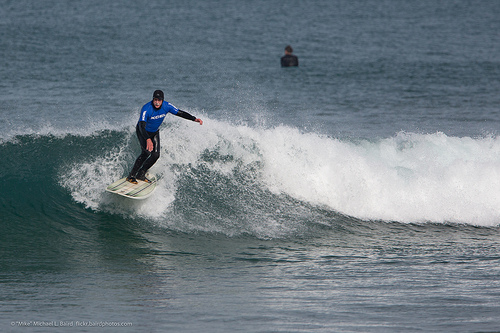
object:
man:
[125, 89, 201, 184]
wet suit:
[123, 101, 194, 179]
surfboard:
[104, 174, 162, 200]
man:
[277, 43, 300, 68]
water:
[1, 0, 497, 333]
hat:
[153, 89, 164, 98]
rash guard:
[138, 100, 177, 132]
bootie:
[125, 175, 137, 185]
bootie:
[137, 174, 151, 182]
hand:
[144, 139, 156, 153]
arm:
[165, 102, 205, 125]